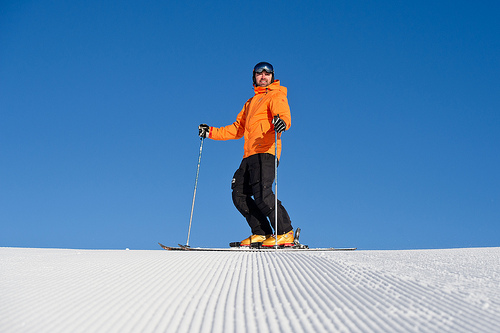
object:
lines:
[0, 252, 500, 333]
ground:
[0, 248, 500, 333]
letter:
[277, 235, 292, 241]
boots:
[240, 230, 295, 247]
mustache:
[260, 79, 270, 87]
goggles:
[254, 67, 273, 73]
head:
[252, 61, 275, 87]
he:
[198, 62, 294, 247]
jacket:
[208, 79, 292, 167]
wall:
[420, 251, 489, 332]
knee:
[232, 190, 251, 204]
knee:
[252, 189, 272, 210]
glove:
[198, 124, 209, 140]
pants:
[231, 153, 294, 236]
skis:
[158, 242, 358, 252]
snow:
[0, 246, 497, 333]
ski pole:
[273, 116, 281, 249]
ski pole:
[184, 137, 204, 248]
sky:
[0, 0, 500, 248]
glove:
[272, 117, 286, 133]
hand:
[272, 118, 286, 133]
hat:
[252, 61, 275, 84]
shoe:
[261, 230, 294, 248]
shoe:
[240, 233, 274, 246]